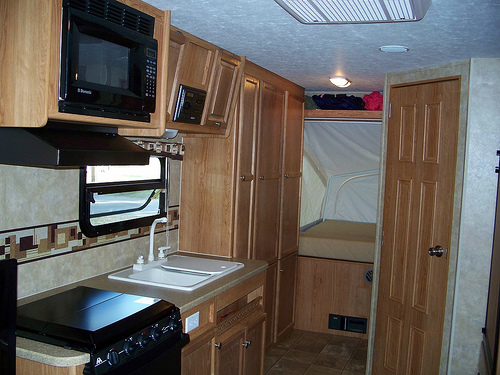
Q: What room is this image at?
A: It is at the kitchen.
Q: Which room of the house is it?
A: It is a kitchen.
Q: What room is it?
A: It is a kitchen.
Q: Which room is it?
A: It is a kitchen.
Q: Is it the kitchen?
A: Yes, it is the kitchen.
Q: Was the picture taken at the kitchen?
A: Yes, it was taken in the kitchen.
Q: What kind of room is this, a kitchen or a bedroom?
A: It is a kitchen.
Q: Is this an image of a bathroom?
A: No, the picture is showing a kitchen.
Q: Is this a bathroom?
A: No, it is a kitchen.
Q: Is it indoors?
A: Yes, it is indoors.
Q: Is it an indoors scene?
A: Yes, it is indoors.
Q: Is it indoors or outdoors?
A: It is indoors.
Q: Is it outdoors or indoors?
A: It is indoors.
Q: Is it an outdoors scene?
A: No, it is indoors.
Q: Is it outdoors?
A: No, it is indoors.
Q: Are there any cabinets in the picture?
A: Yes, there is a cabinet.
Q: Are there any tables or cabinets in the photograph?
A: Yes, there is a cabinet.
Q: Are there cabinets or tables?
A: Yes, there is a cabinet.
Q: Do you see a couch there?
A: No, there are no couches.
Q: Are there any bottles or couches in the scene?
A: No, there are no couches or bottles.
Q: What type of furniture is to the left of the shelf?
A: The piece of furniture is a cabinet.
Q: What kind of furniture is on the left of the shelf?
A: The piece of furniture is a cabinet.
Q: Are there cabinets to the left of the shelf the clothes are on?
A: Yes, there is a cabinet to the left of the shelf.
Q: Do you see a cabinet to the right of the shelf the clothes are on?
A: No, the cabinet is to the left of the shelf.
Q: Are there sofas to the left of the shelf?
A: No, there is a cabinet to the left of the shelf.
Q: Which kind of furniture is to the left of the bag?
A: The piece of furniture is a cabinet.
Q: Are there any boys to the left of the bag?
A: No, there is a cabinet to the left of the bag.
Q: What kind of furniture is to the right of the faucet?
A: The piece of furniture is a cabinet.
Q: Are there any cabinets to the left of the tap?
A: No, the cabinet is to the right of the tap.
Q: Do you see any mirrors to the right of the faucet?
A: No, there is a cabinet to the right of the faucet.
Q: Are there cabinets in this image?
A: Yes, there is a cabinet.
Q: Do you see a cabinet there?
A: Yes, there is a cabinet.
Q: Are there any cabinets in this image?
A: Yes, there is a cabinet.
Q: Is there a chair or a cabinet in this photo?
A: Yes, there is a cabinet.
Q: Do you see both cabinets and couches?
A: No, there is a cabinet but no couches.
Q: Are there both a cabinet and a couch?
A: No, there is a cabinet but no couches.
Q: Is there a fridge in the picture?
A: No, there are no refrigerators.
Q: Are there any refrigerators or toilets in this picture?
A: No, there are no refrigerators or toilets.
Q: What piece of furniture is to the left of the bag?
A: The piece of furniture is a cabinet.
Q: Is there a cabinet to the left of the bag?
A: Yes, there is a cabinet to the left of the bag.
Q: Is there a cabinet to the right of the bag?
A: No, the cabinet is to the left of the bag.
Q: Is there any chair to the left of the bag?
A: No, there is a cabinet to the left of the bag.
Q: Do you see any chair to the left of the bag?
A: No, there is a cabinet to the left of the bag.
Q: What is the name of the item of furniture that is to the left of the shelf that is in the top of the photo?
A: The piece of furniture is a cabinet.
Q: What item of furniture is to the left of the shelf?
A: The piece of furniture is a cabinet.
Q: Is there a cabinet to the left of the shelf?
A: Yes, there is a cabinet to the left of the shelf.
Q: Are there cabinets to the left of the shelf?
A: Yes, there is a cabinet to the left of the shelf.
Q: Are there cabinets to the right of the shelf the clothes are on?
A: No, the cabinet is to the left of the shelf.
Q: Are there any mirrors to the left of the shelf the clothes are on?
A: No, there is a cabinet to the left of the shelf.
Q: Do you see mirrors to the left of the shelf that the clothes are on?
A: No, there is a cabinet to the left of the shelf.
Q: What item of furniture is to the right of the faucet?
A: The piece of furniture is a cabinet.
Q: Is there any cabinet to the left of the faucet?
A: No, the cabinet is to the right of the faucet.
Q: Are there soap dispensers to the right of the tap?
A: No, there is a cabinet to the right of the tap.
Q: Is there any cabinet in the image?
A: Yes, there is a cabinet.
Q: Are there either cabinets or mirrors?
A: Yes, there is a cabinet.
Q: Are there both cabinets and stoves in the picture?
A: Yes, there are both a cabinet and a stove.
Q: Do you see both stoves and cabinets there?
A: Yes, there are both a cabinet and a stove.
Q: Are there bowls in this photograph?
A: No, there are no bowls.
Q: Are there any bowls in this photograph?
A: No, there are no bowls.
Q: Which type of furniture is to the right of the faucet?
A: The piece of furniture is a cabinet.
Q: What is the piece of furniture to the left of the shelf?
A: The piece of furniture is a cabinet.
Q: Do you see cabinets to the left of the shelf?
A: Yes, there is a cabinet to the left of the shelf.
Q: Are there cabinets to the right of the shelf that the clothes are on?
A: No, the cabinet is to the left of the shelf.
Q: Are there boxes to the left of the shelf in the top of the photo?
A: No, there is a cabinet to the left of the shelf.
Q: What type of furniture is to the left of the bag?
A: The piece of furniture is a cabinet.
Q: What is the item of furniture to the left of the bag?
A: The piece of furniture is a cabinet.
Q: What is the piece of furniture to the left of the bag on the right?
A: The piece of furniture is a cabinet.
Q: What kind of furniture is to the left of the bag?
A: The piece of furniture is a cabinet.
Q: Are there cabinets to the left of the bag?
A: Yes, there is a cabinet to the left of the bag.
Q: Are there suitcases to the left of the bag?
A: No, there is a cabinet to the left of the bag.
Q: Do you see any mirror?
A: No, there are no mirrors.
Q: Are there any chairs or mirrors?
A: No, there are no mirrors or chairs.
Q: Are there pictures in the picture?
A: No, there are no pictures.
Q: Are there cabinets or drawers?
A: Yes, there is a cabinet.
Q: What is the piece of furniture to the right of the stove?
A: The piece of furniture is a cabinet.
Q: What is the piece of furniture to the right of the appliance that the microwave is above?
A: The piece of furniture is a cabinet.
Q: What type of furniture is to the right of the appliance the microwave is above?
A: The piece of furniture is a cabinet.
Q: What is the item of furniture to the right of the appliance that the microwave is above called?
A: The piece of furniture is a cabinet.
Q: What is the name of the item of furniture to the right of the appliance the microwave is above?
A: The piece of furniture is a cabinet.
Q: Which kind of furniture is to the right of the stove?
A: The piece of furniture is a cabinet.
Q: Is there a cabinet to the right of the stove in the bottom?
A: Yes, there is a cabinet to the right of the stove.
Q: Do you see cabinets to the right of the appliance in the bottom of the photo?
A: Yes, there is a cabinet to the right of the stove.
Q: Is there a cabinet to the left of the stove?
A: No, the cabinet is to the right of the stove.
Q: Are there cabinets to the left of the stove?
A: No, the cabinet is to the right of the stove.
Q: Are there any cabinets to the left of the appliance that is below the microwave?
A: No, the cabinet is to the right of the stove.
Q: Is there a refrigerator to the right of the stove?
A: No, there is a cabinet to the right of the stove.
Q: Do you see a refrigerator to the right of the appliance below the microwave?
A: No, there is a cabinet to the right of the stove.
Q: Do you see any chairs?
A: No, there are no chairs.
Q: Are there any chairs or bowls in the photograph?
A: No, there are no chairs or bowls.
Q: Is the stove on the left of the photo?
A: Yes, the stove is on the left of the image.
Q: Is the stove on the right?
A: No, the stove is on the left of the image.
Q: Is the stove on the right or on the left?
A: The stove is on the left of the image.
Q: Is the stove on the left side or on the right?
A: The stove is on the left of the image.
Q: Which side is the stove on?
A: The stove is on the left of the image.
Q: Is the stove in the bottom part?
A: Yes, the stove is in the bottom of the image.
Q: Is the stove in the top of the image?
A: No, the stove is in the bottom of the image.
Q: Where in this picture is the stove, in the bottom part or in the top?
A: The stove is in the bottom of the image.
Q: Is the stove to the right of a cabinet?
A: No, the stove is to the left of a cabinet.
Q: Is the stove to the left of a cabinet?
A: Yes, the stove is to the left of a cabinet.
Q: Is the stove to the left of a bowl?
A: No, the stove is to the left of a cabinet.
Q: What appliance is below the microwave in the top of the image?
A: The appliance is a stove.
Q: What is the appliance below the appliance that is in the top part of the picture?
A: The appliance is a stove.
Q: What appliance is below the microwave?
A: The appliance is a stove.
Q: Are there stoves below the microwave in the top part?
A: Yes, there is a stove below the microwave.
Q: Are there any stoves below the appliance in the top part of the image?
A: Yes, there is a stove below the microwave.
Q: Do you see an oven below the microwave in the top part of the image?
A: No, there is a stove below the microwave.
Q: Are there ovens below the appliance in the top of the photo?
A: No, there is a stove below the microwave.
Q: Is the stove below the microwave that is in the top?
A: Yes, the stove is below the microwave.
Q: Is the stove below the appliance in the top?
A: Yes, the stove is below the microwave.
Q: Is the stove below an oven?
A: No, the stove is below the microwave.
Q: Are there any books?
A: No, there are no books.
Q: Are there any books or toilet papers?
A: No, there are no books or toilet papers.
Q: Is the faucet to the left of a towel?
A: No, the faucet is to the left of the cabinet.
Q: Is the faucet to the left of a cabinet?
A: Yes, the faucet is to the left of a cabinet.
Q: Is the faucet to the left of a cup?
A: No, the faucet is to the left of a cabinet.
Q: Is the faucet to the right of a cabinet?
A: No, the faucet is to the left of a cabinet.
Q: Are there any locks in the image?
A: No, there are no locks.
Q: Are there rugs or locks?
A: No, there are no locks or rugs.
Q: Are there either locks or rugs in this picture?
A: No, there are no locks or rugs.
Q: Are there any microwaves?
A: Yes, there is a microwave.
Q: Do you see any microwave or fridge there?
A: Yes, there is a microwave.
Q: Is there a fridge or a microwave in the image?
A: Yes, there is a microwave.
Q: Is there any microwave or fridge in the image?
A: Yes, there is a microwave.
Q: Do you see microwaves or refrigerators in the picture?
A: Yes, there is a microwave.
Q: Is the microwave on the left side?
A: Yes, the microwave is on the left of the image.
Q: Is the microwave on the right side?
A: No, the microwave is on the left of the image.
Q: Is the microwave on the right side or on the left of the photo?
A: The microwave is on the left of the image.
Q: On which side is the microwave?
A: The microwave is on the left of the image.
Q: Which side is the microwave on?
A: The microwave is on the left of the image.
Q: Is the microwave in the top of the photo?
A: Yes, the microwave is in the top of the image.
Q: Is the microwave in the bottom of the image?
A: No, the microwave is in the top of the image.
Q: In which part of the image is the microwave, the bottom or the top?
A: The microwave is in the top of the image.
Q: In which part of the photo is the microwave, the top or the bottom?
A: The microwave is in the top of the image.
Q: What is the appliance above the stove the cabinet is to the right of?
A: The appliance is a microwave.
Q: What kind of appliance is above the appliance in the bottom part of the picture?
A: The appliance is a microwave.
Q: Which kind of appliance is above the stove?
A: The appliance is a microwave.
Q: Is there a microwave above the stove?
A: Yes, there is a microwave above the stove.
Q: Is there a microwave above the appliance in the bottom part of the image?
A: Yes, there is a microwave above the stove.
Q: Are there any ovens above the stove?
A: No, there is a microwave above the stove.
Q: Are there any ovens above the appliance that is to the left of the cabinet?
A: No, there is a microwave above the stove.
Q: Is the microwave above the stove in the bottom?
A: Yes, the microwave is above the stove.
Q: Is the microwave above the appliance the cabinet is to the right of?
A: Yes, the microwave is above the stove.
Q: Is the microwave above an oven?
A: No, the microwave is above the stove.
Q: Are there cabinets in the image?
A: Yes, there is a cabinet.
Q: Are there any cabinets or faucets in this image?
A: Yes, there is a cabinet.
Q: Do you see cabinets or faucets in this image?
A: Yes, there is a cabinet.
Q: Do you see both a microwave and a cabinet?
A: Yes, there are both a cabinet and a microwave.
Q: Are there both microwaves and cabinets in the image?
A: Yes, there are both a cabinet and a microwave.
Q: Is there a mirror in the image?
A: No, there are no mirrors.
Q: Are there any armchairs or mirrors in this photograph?
A: No, there are no mirrors or armchairs.